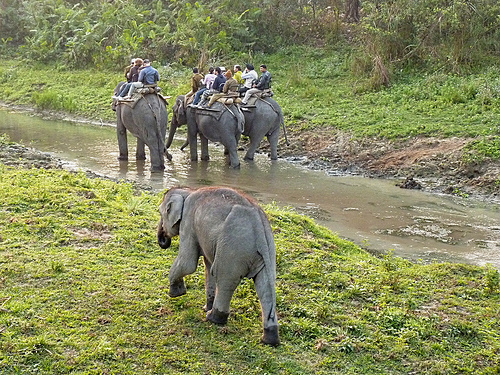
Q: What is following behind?
A: The baby elephant.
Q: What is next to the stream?
A: The tropical plants.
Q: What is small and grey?
A: The elephant.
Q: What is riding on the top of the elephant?
A: The people.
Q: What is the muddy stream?
A: Small.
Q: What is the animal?
A: Elephant.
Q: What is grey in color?
A: The elephant.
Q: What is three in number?
A: The elephants.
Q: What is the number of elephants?
A: 4.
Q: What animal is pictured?
A: Elephants.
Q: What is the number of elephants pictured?
A: Four.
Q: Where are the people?
A: On top of the elephants.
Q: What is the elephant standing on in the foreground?
A: Grass.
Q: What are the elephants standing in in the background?
A: Stream.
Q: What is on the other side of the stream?
A: Grass and bushes.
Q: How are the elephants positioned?
A: Standing.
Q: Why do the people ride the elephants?
A: For transport.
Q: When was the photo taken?
A: During day hours.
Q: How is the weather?
A: Damp.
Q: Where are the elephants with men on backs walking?
A: In stream.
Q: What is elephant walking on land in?
A: Grass.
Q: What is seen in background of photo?
A: Vegetation.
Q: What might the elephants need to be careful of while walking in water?
A: Rocks.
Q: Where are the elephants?
A: On the grass and in the water.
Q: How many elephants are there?
A: Four.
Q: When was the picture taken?
A: Daytime.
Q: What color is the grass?
A: Green.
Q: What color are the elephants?
A: Gray.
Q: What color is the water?
A: Brown.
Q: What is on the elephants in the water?
A: Riders.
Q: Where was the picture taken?
A: At a safari.